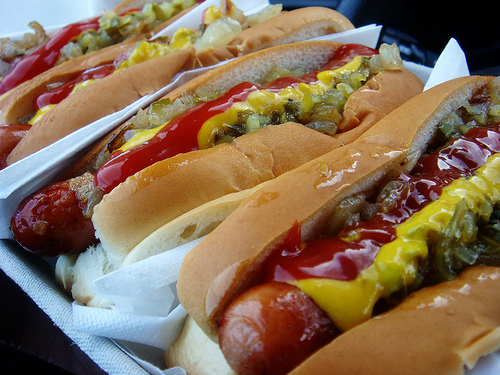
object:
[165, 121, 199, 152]
ketchup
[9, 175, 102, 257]
hotdog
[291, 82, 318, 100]
mustard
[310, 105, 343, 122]
relish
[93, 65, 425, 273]
bun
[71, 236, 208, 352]
napkin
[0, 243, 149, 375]
plate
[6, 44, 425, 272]
food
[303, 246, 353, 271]
ketchup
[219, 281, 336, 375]
hotdog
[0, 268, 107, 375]
table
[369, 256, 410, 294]
mustard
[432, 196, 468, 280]
relish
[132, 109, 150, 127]
onions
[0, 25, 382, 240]
napkin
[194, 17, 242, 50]
onions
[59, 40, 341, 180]
bun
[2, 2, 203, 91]
snack